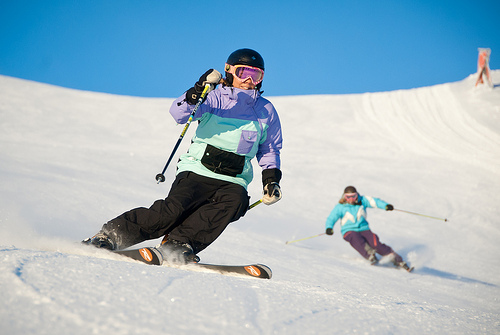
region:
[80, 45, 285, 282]
female in ski suit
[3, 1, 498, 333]
snowy landscape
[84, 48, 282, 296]
female skiing in the snow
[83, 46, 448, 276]
two people skiing in snow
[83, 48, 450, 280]
two people wearing ski suits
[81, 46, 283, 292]
female in pink ski goggles wearing black gloves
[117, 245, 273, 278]
black, white and orange skis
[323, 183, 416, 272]
man in blue and white ski jacket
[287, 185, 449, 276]
skier holding two ski poles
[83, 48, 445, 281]
two people skiing downhill in snow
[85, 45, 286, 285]
a person is skiing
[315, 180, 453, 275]
a person is skiing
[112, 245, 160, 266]
a black and orange ski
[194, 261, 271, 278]
a black and orange ski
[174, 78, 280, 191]
a purple and blue jacket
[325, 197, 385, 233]
a white and blue jacket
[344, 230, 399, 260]
purple and orange pants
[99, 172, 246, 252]
a pair of black ski pants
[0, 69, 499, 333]
a snow covered slop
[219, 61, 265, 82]
pink ski goggles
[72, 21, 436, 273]
two skiers coming down the mountain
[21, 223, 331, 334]
tracks in the snow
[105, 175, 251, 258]
black pants the skier is wearing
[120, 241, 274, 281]
black skies with orange and white logo on the skis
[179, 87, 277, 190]
purple, light blue, and black coat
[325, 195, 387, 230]
blue and white coat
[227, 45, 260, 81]
black helmet skier is wearing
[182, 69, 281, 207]
black and white gloves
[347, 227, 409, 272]
purple pants background skier is wearing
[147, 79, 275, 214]
black and yellow ski poles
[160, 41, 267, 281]
person skiing on ski slope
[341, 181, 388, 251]
person skiing on ski slope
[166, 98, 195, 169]
ski pole in skier's hand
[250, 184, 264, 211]
ski pole in skier's hand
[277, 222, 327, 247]
ski pole in skier's hand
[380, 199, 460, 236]
ski pole in skier's hand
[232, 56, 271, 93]
purple goggles on skier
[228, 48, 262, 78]
black helmet on skier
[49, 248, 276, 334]
thick snow on ski slope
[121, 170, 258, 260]
black pants in skier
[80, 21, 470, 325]
two people are skiing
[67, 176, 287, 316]
the woman is wearing black snow pants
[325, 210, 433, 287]
the girl is wearing purple snow pants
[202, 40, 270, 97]
the woman is wearing a helmet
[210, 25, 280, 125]
the woman has glasses on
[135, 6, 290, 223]
the woman is holding a ski stick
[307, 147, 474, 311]
the girl is having fun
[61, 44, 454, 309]
they are skiing in snow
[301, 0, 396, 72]
the sky is clear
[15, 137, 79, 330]
the snow is white